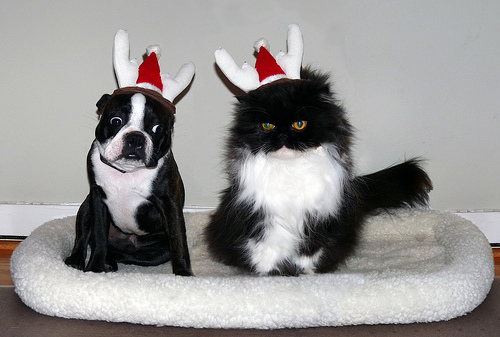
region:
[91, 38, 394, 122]
two animals are wearing hats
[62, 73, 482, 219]
the cat and dog are the same color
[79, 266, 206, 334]
the bed is white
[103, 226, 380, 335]
two animals are sitting on a bed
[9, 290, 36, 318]
the ground is made of wood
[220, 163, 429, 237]
the cat has a white neck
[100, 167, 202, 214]
the dog has a white neck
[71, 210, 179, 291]
the dog has black legs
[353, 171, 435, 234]
the cat has a black tail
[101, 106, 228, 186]
the dog has black eyes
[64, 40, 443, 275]
Two animals are pictured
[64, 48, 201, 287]
This is a dog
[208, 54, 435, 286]
This is a cat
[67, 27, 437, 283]
Both animals are wearing santa hats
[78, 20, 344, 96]
Both of the santa hats have antlers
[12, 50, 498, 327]
The animals are sitting on a pet bed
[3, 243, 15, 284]
The floor is made of hardwood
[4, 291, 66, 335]
There is an area rug on the hardwood floor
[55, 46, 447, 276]
Both animals are facing the camera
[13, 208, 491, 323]
The bed is soft and fluffy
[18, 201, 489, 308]
The animals are sitting on a pet bed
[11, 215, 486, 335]
The bed is soft and plush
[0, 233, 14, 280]
The floor is made of hardwood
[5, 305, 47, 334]
There is an area rug on the hardwood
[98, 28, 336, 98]
Both animals are wearing Santa hats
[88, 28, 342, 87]
Both Santa hats have antlers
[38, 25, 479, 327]
Two animals on a bed.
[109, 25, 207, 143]
Dog with a hat.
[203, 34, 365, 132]
Cat with a hat.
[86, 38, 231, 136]
Red hat on the dog.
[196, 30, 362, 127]
Red hat on the cat.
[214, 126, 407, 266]
Black and white cat.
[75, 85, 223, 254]
Black and white dog.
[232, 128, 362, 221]
Fur on the cat.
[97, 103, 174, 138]
Eyes of the dog.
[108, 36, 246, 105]
Antlers on the dog.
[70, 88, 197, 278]
the black and white little bug dog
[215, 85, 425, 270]
the black and white fluffy cat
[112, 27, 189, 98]
a red and white little hat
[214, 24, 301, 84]
a red and white little hat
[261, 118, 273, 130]
the black and orange eye of the cat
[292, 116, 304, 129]
the black and orange eye of the cat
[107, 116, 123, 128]
the black and white eye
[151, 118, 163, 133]
the black and white eye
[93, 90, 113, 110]
the black ear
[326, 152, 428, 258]
the black fluffy tail